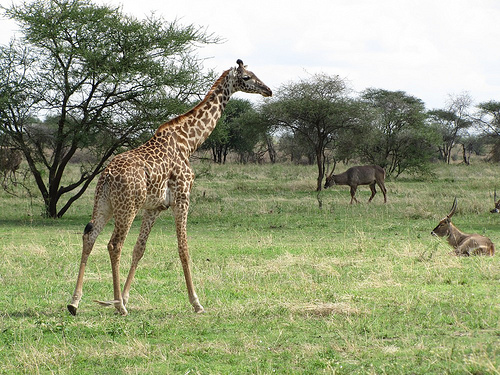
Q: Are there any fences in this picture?
A: No, there are no fences.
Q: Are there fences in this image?
A: No, there are no fences.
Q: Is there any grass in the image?
A: Yes, there is grass.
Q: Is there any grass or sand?
A: Yes, there is grass.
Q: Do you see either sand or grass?
A: Yes, there is grass.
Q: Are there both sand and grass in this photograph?
A: No, there is grass but no sand.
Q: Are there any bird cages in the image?
A: No, there are no bird cages.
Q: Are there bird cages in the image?
A: No, there are no bird cages.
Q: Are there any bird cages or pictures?
A: No, there are no bird cages or pictures.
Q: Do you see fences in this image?
A: No, there are no fences.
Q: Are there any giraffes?
A: Yes, there is a giraffe.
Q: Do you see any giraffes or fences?
A: Yes, there is a giraffe.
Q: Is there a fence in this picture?
A: No, there are no fences.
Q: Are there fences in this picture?
A: No, there are no fences.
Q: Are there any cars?
A: No, there are no cars.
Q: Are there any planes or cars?
A: No, there are no cars or planes.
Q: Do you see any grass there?
A: Yes, there is grass.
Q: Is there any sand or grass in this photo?
A: Yes, there is grass.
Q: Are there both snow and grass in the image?
A: No, there is grass but no snow.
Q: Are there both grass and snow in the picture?
A: No, there is grass but no snow.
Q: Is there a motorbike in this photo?
A: No, there are no motorcycles.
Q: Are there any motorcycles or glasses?
A: No, there are no motorcycles or glasses.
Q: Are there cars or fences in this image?
A: No, there are no fences or cars.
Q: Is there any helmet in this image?
A: No, there are no helmets.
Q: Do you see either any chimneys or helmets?
A: No, there are no helmets or chimneys.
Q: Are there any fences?
A: No, there are no fences.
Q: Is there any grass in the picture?
A: Yes, there is grass.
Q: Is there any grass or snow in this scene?
A: Yes, there is grass.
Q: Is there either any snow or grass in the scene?
A: Yes, there is grass.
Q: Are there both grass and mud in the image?
A: No, there is grass but no mud.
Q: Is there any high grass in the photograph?
A: Yes, there is high grass.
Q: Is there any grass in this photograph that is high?
A: Yes, there is grass that is high.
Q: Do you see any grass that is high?
A: Yes, there is grass that is high.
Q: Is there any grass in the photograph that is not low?
A: Yes, there is high grass.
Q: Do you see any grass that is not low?
A: Yes, there is high grass.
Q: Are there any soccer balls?
A: No, there are no soccer balls.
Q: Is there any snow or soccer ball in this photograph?
A: No, there are no soccer balls or snow.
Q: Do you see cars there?
A: No, there are no cars.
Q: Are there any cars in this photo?
A: No, there are no cars.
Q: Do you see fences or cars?
A: No, there are no cars or fences.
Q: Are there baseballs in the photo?
A: No, there are no baseballs.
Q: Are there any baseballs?
A: No, there are no baseballs.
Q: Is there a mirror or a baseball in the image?
A: No, there are no baseballs or mirrors.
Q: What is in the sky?
A: The clouds are in the sky.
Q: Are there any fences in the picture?
A: No, there are no fences.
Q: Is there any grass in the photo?
A: Yes, there is grass.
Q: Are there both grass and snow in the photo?
A: No, there is grass but no snow.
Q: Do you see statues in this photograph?
A: No, there are no statues.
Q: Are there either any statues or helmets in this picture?
A: No, there are no statues or helmets.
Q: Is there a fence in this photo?
A: No, there are no fences.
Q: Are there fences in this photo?
A: No, there are no fences.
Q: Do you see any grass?
A: Yes, there is grass.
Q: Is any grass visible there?
A: Yes, there is grass.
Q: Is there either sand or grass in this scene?
A: Yes, there is grass.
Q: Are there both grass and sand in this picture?
A: No, there is grass but no sand.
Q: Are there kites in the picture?
A: No, there are no kites.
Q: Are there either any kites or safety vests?
A: No, there are no kites or safety vests.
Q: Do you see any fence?
A: No, there are no fences.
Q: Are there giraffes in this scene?
A: Yes, there is a giraffe.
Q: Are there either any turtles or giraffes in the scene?
A: Yes, there is a giraffe.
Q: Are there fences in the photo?
A: No, there are no fences.